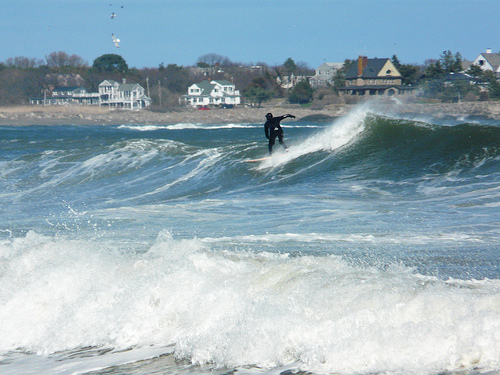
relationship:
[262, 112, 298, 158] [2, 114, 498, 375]
man surfing in ocean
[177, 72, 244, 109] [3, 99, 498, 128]
house by beach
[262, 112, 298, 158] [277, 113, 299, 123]
man holding out arm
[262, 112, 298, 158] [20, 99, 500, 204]
man surfing on wave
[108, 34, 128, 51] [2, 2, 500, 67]
bird up in sky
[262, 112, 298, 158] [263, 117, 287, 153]
man inside of wet suit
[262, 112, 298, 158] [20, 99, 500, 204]
man rides wave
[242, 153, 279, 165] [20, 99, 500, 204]
surfboard rides wave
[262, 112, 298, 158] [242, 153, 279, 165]
man on top of surfboard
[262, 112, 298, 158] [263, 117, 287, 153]
man wears wet suit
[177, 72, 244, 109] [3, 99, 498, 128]
house on edge of beach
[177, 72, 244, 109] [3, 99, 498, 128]
house on beach